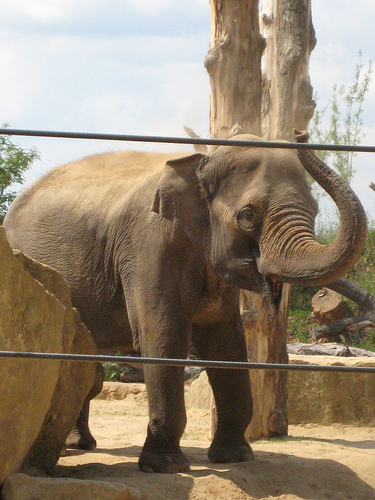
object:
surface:
[93, 465, 364, 500]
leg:
[136, 285, 188, 470]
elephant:
[3, 127, 367, 474]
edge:
[56, 295, 101, 355]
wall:
[2, 220, 99, 487]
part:
[296, 266, 310, 271]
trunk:
[258, 128, 369, 284]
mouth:
[261, 271, 285, 323]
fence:
[7, 129, 374, 164]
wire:
[0, 348, 372, 372]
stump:
[211, 285, 289, 439]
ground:
[81, 397, 372, 499]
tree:
[203, 0, 267, 142]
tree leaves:
[0, 122, 41, 220]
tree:
[308, 289, 363, 343]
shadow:
[218, 446, 373, 499]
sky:
[4, 0, 199, 112]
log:
[306, 312, 374, 344]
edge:
[183, 461, 192, 468]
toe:
[165, 461, 192, 475]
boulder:
[285, 354, 372, 425]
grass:
[366, 265, 374, 287]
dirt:
[115, 416, 129, 426]